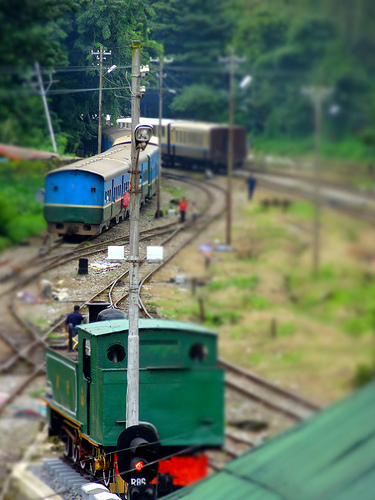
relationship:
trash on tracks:
[4, 266, 82, 311] [5, 225, 205, 306]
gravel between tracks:
[25, 176, 189, 324] [0, 162, 318, 473]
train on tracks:
[92, 110, 254, 179] [6, 180, 225, 384]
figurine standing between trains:
[179, 199, 188, 222] [75, 127, 151, 253]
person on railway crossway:
[243, 168, 261, 202] [0, 164, 375, 498]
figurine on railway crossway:
[179, 199, 188, 222] [0, 164, 375, 498]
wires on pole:
[49, 38, 203, 120] [107, 44, 158, 490]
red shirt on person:
[179, 200, 187, 211] [174, 191, 191, 224]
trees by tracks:
[234, 395, 260, 434] [227, 346, 300, 426]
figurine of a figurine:
[178, 196, 187, 221] [179, 199, 188, 222]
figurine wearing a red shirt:
[179, 199, 188, 222] [180, 203, 188, 212]